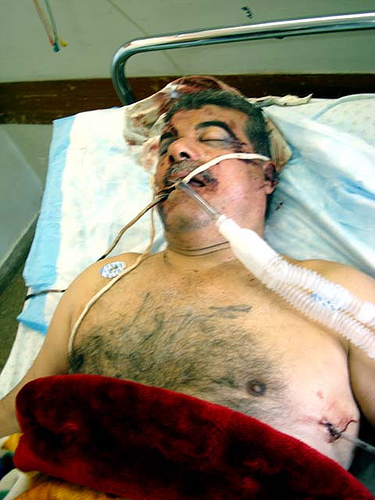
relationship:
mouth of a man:
[160, 170, 207, 193] [104, 90, 287, 364]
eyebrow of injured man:
[195, 117, 235, 137] [5, 87, 374, 500]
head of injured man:
[151, 86, 281, 255] [5, 87, 374, 479]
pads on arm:
[100, 259, 126, 278] [0, 252, 138, 436]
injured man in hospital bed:
[5, 87, 374, 500] [1, 11, 372, 485]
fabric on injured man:
[6, 371, 373, 499] [5, 87, 374, 500]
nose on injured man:
[164, 133, 202, 164] [5, 87, 374, 500]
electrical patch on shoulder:
[72, 240, 121, 296] [6, 223, 152, 340]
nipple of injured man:
[228, 361, 277, 408] [5, 87, 374, 500]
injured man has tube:
[5, 87, 374, 500] [163, 176, 222, 218]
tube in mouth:
[163, 176, 222, 218] [168, 158, 254, 236]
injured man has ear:
[5, 87, 374, 500] [259, 158, 277, 193]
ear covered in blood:
[259, 158, 277, 193] [262, 157, 279, 205]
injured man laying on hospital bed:
[5, 87, 374, 500] [18, 111, 365, 496]